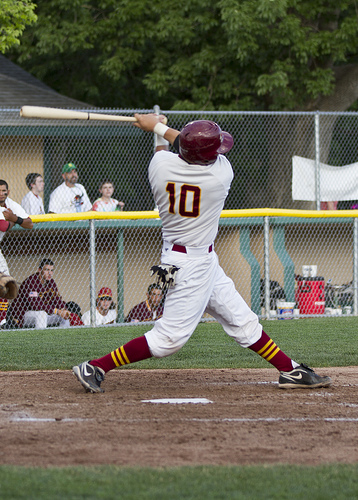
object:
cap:
[97, 286, 114, 298]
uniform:
[143, 148, 263, 356]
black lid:
[298, 275, 322, 280]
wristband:
[153, 121, 170, 137]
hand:
[133, 112, 159, 130]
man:
[47, 161, 93, 213]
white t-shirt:
[47, 181, 94, 213]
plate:
[137, 396, 212, 403]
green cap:
[61, 160, 78, 173]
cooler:
[296, 276, 326, 314]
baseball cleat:
[276, 365, 331, 388]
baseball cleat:
[71, 357, 106, 394]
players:
[7, 257, 70, 328]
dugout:
[0, 230, 356, 329]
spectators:
[0, 179, 33, 298]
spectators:
[21, 172, 44, 217]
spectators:
[92, 178, 125, 212]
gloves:
[149, 265, 178, 287]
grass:
[0, 461, 357, 499]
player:
[124, 281, 166, 321]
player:
[81, 286, 117, 325]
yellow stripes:
[109, 349, 122, 367]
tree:
[0, 0, 38, 56]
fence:
[0, 108, 357, 331]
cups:
[302, 264, 310, 278]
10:
[166, 182, 201, 217]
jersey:
[147, 148, 235, 249]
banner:
[291, 155, 357, 203]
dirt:
[0, 365, 357, 466]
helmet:
[177, 118, 233, 166]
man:
[71, 112, 330, 392]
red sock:
[248, 329, 294, 371]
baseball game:
[0, 105, 357, 499]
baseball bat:
[20, 104, 168, 126]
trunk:
[267, 113, 334, 211]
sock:
[88, 335, 151, 373]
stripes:
[265, 345, 280, 360]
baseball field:
[0, 316, 357, 498]